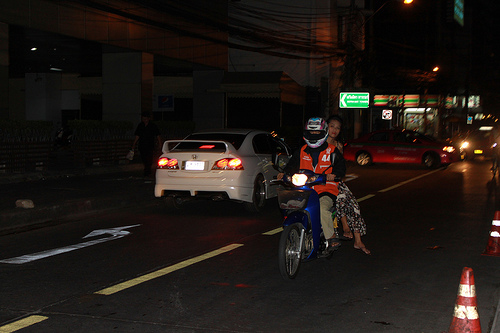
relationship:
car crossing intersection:
[344, 128, 455, 170] [345, 158, 482, 188]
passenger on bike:
[326, 116, 374, 256] [267, 161, 339, 282]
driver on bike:
[277, 117, 339, 256] [267, 161, 339, 282]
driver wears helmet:
[281, 99, 338, 256] [295, 110, 331, 150]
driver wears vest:
[281, 99, 338, 256] [297, 141, 334, 188]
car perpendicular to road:
[344, 120, 455, 170] [349, 157, 489, 329]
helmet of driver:
[299, 113, 329, 145] [277, 117, 339, 256]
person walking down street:
[130, 104, 157, 187] [0, 152, 496, 331]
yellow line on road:
[2, 307, 47, 331] [186, 280, 410, 322]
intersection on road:
[378, 158, 465, 194] [0, 136, 500, 331]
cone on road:
[442, 246, 487, 331] [154, 165, 481, 287]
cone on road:
[442, 266, 487, 332] [98, 199, 450, 330]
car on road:
[108, 103, 293, 225] [113, 189, 253, 303]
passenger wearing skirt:
[289, 109, 342, 255] [334, 180, 370, 237]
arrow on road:
[13, 201, 164, 282] [35, 166, 196, 316]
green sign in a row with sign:
[339, 91, 369, 108] [373, 93, 481, 107]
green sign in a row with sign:
[339, 91, 369, 108] [380, 107, 394, 119]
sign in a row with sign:
[373, 93, 481, 107] [380, 107, 394, 119]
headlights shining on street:
[443, 138, 471, 157] [0, 152, 496, 331]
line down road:
[88, 237, 273, 289] [0, 145, 500, 333]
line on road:
[93, 243, 244, 296] [0, 136, 500, 331]